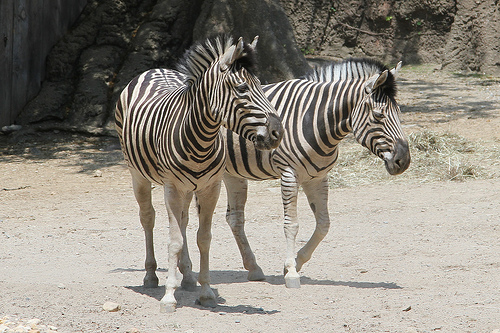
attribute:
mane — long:
[168, 26, 261, 93]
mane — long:
[297, 52, 402, 104]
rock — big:
[22, 7, 112, 127]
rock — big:
[130, 3, 290, 33]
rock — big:
[300, 2, 497, 60]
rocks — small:
[87, 290, 134, 321]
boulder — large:
[5, 1, 310, 141]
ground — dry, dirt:
[0, 60, 497, 331]